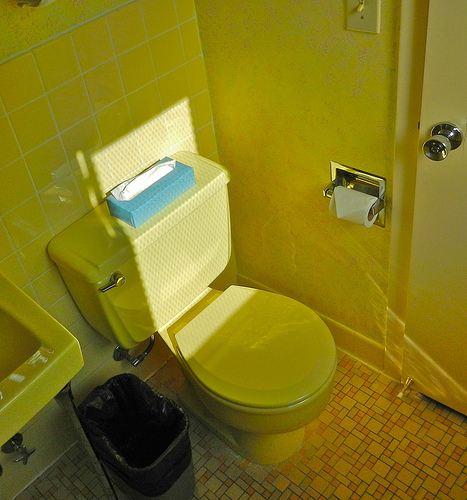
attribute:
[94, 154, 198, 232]
box — blue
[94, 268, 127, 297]
lever — silver, metal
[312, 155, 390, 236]
dispenser — silver, metal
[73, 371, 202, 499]
garbage can — black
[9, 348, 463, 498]
tile — patterned, nice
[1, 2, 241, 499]
wall — tile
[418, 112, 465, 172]
handle — silver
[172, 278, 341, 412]
toilet seat — down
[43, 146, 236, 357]
toilet tank — light